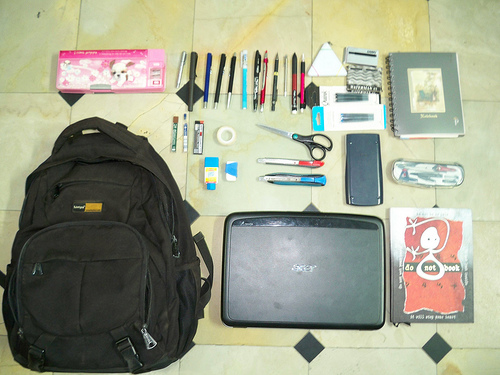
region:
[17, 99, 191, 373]
the bag is black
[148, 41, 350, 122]
the pens are lined up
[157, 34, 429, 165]
the pens are lined up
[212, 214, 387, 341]
the laptop is closed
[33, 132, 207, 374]
the bag is black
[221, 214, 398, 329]
the brand is acer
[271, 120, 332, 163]
the scissors hadles are black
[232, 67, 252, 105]
the pen is blue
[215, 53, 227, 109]
the pen is black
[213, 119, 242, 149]
tape is on the table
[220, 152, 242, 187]
the rubber is blue and white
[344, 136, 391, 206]
the culculator is upside down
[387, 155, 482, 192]
geometrical set is on the table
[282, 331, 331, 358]
blue squares on table top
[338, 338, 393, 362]
edge of white tile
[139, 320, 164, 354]
silver zipper on book bag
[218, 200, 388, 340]
cover of black laptop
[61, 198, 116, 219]
black and yellow label on book bag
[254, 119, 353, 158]
black and silver scissors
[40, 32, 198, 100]
box of pink tissue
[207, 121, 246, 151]
roll of white scotch tape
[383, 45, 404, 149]
spiral on side of note book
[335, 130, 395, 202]
gray calculator in case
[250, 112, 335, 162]
A pair of black scissors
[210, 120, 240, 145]
A roll of clear tape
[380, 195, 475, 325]
A black/red book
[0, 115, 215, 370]
A black backpack on the floor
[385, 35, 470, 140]
A blue/white notebook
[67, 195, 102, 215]
A black/orange logo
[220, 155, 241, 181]
A blue/white eraser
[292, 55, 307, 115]
A black/pink mechanical pencil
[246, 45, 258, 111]
A black marker on the floor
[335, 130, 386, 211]
A blue calculator on the floor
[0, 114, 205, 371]
a black pack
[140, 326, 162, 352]
it is a zipper on the backpack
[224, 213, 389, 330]
it is a black top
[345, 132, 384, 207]
it is a black cell phone cover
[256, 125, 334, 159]
it is a pair of scissors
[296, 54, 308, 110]
a pink and black pencil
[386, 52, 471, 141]
it is a notebook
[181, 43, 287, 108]
a group of pens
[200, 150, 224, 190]
it is some white out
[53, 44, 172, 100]
pink box with puppy on it